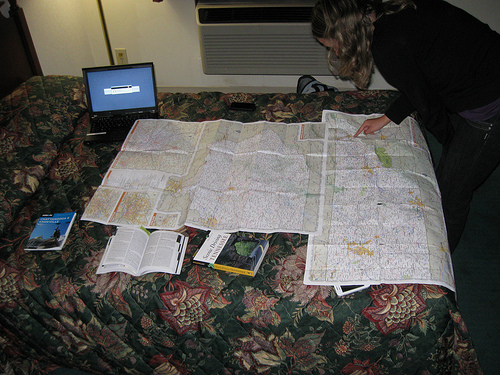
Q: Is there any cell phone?
A: Yes, there is a cell phone.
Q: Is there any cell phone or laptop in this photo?
A: Yes, there is a cell phone.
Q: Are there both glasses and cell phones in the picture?
A: No, there is a cell phone but no glasses.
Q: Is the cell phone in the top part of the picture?
A: Yes, the cell phone is in the top of the image.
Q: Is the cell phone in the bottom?
A: No, the cell phone is in the top of the image.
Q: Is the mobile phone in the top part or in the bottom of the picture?
A: The mobile phone is in the top of the image.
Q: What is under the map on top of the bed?
A: The cell phone is under the map.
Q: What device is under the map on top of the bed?
A: The device is a cell phone.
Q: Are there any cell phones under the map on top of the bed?
A: Yes, there is a cell phone under the map.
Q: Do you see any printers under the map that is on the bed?
A: No, there is a cell phone under the map.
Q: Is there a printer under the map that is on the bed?
A: No, there is a cell phone under the map.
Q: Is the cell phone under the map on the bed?
A: Yes, the cell phone is under the map.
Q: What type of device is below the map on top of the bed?
A: The device is a cell phone.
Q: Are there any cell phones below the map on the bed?
A: Yes, there is a cell phone below the map.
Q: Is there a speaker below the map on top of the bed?
A: No, there is a cell phone below the map.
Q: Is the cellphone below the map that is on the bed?
A: Yes, the cellphone is below the map.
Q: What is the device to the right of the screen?
A: The device is a cell phone.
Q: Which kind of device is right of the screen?
A: The device is a cell phone.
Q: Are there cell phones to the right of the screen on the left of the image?
A: Yes, there is a cell phone to the right of the screen.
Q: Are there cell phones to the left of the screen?
A: No, the cell phone is to the right of the screen.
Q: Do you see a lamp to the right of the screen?
A: No, there is a cell phone to the right of the screen.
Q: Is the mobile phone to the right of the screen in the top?
A: Yes, the mobile phone is to the right of the screen.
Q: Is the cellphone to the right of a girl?
A: No, the cellphone is to the right of the screen.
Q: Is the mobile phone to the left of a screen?
A: No, the mobile phone is to the right of a screen.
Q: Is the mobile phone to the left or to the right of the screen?
A: The mobile phone is to the right of the screen.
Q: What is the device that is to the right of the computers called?
A: The device is a cell phone.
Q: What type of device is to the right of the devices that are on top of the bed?
A: The device is a cell phone.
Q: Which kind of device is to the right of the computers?
A: The device is a cell phone.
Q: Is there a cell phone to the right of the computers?
A: Yes, there is a cell phone to the right of the computers.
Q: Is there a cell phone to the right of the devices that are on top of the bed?
A: Yes, there is a cell phone to the right of the computers.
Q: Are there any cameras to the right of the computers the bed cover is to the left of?
A: No, there is a cell phone to the right of the computers.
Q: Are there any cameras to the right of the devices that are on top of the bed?
A: No, there is a cell phone to the right of the computers.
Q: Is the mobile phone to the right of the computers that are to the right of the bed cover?
A: Yes, the mobile phone is to the right of the computers.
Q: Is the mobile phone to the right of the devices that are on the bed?
A: Yes, the mobile phone is to the right of the computers.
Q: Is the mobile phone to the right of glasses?
A: No, the mobile phone is to the right of the computers.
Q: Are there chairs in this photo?
A: No, there are no chairs.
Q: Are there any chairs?
A: No, there are no chairs.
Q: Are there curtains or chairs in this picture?
A: No, there are no chairs or curtains.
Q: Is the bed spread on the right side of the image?
A: No, the bed spread is on the left of the image.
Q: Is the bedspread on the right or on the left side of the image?
A: The bedspread is on the left of the image.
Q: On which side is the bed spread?
A: The bed spread is on the left of the image.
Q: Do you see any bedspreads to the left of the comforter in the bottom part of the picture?
A: Yes, there is a bedspread to the left of the bed cover.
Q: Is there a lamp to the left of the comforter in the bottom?
A: No, there is a bedspread to the left of the comforter.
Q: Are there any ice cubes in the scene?
A: No, there are no ice cubes.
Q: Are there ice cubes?
A: No, there are no ice cubes.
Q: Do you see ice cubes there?
A: No, there are no ice cubes.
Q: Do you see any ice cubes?
A: No, there are no ice cubes.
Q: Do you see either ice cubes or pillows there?
A: No, there are no ice cubes or pillows.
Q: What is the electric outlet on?
A: The electric outlet is on the wall.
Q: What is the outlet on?
A: The electric outlet is on the wall.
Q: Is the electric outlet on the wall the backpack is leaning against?
A: Yes, the electric outlet is on the wall.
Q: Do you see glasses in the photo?
A: No, there are no glasses.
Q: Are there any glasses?
A: No, there are no glasses.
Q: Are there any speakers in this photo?
A: No, there are no speakers.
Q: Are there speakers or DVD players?
A: No, there are no speakers or DVD players.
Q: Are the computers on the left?
A: Yes, the computers are on the left of the image.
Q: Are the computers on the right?
A: No, the computers are on the left of the image.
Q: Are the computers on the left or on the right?
A: The computers are on the left of the image.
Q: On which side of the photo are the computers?
A: The computers are on the left of the image.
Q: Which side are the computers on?
A: The computers are on the left of the image.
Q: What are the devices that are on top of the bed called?
A: The devices are computers.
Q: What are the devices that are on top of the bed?
A: The devices are computers.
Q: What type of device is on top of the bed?
A: The devices are computers.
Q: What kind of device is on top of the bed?
A: The devices are computers.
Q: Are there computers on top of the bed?
A: Yes, there are computers on top of the bed.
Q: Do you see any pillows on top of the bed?
A: No, there are computers on top of the bed.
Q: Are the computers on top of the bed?
A: Yes, the computers are on top of the bed.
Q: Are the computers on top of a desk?
A: No, the computers are on top of the bed.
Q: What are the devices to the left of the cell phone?
A: The devices are computers.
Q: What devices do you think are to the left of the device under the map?
A: The devices are computers.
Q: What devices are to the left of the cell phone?
A: The devices are computers.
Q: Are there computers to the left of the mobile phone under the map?
A: Yes, there are computers to the left of the mobile phone.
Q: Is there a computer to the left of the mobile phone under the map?
A: Yes, there are computers to the left of the mobile phone.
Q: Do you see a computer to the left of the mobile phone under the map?
A: Yes, there are computers to the left of the mobile phone.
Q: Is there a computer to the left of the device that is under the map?
A: Yes, there are computers to the left of the mobile phone.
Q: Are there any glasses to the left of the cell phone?
A: No, there are computers to the left of the cell phone.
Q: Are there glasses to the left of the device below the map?
A: No, there are computers to the left of the cell phone.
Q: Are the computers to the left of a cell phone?
A: Yes, the computers are to the left of a cell phone.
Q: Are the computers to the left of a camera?
A: No, the computers are to the left of a cell phone.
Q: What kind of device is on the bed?
A: The devices are computers.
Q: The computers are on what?
A: The computers are on the bed.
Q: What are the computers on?
A: The computers are on the bed.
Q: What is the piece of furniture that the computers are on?
A: The piece of furniture is a bed.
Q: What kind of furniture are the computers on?
A: The computers are on the bed.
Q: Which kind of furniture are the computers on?
A: The computers are on the bed.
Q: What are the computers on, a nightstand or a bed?
A: The computers are on a bed.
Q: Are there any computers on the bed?
A: Yes, there are computers on the bed.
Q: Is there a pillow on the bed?
A: No, there are computers on the bed.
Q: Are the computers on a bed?
A: Yes, the computers are on a bed.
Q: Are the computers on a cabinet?
A: No, the computers are on a bed.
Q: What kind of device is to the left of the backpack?
A: The devices are computers.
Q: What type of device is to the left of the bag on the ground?
A: The devices are computers.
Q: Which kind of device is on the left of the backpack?
A: The devices are computers.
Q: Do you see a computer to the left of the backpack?
A: Yes, there are computers to the left of the backpack.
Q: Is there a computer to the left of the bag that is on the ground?
A: Yes, there are computers to the left of the backpack.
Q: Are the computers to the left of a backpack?
A: Yes, the computers are to the left of a backpack.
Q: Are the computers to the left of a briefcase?
A: No, the computers are to the left of a backpack.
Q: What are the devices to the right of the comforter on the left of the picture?
A: The devices are computers.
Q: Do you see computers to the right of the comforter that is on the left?
A: Yes, there are computers to the right of the comforter.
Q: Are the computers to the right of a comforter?
A: Yes, the computers are to the right of a comforter.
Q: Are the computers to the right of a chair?
A: No, the computers are to the right of a comforter.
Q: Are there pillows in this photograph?
A: No, there are no pillows.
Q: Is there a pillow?
A: No, there are no pillows.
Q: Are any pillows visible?
A: No, there are no pillows.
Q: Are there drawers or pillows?
A: No, there are no pillows or drawers.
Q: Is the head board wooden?
A: Yes, the head board is wooden.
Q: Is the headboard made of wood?
A: Yes, the headboard is made of wood.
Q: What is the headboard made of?
A: The headboard is made of wood.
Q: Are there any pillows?
A: No, there are no pillows.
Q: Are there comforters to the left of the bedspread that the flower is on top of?
A: Yes, there is a comforter to the left of the bedspread.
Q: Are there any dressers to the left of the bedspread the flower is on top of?
A: No, there is a comforter to the left of the bedspread.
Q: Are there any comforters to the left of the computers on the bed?
A: Yes, there is a comforter to the left of the computers.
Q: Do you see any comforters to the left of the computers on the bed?
A: Yes, there is a comforter to the left of the computers.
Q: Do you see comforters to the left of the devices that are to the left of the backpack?
A: Yes, there is a comforter to the left of the computers.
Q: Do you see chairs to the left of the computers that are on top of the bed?
A: No, there is a comforter to the left of the computers.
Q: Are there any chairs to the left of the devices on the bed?
A: No, there is a comforter to the left of the computers.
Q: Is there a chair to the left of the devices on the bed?
A: No, there is a comforter to the left of the computers.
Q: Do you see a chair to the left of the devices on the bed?
A: No, there is a comforter to the left of the computers.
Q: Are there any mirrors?
A: No, there are no mirrors.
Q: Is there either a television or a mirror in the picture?
A: No, there are no mirrors or televisions.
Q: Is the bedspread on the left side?
A: Yes, the bedspread is on the left of the image.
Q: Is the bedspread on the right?
A: No, the bedspread is on the left of the image.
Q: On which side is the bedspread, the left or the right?
A: The bedspread is on the left of the image.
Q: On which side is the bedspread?
A: The bedspread is on the left of the image.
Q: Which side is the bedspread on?
A: The bedspread is on the left of the image.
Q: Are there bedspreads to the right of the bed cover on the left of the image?
A: Yes, there is a bedspread to the right of the bed cover.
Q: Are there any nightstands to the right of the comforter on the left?
A: No, there is a bedspread to the right of the quilt.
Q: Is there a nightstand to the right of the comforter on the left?
A: No, there is a bedspread to the right of the quilt.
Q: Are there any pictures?
A: No, there are no pictures.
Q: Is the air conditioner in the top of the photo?
A: Yes, the air conditioner is in the top of the image.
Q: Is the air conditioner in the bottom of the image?
A: No, the air conditioner is in the top of the image.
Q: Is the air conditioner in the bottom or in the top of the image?
A: The air conditioner is in the top of the image.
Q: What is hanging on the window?
A: The air conditioner is hanging on the window.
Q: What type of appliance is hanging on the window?
A: The appliance is an air conditioner.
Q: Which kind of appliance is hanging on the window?
A: The appliance is an air conditioner.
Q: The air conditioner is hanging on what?
A: The air conditioner is hanging on the window.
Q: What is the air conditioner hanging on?
A: The air conditioner is hanging on the window.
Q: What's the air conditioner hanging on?
A: The air conditioner is hanging on the window.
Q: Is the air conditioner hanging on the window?
A: Yes, the air conditioner is hanging on the window.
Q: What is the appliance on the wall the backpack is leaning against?
A: The appliance is an air conditioner.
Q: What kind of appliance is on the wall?
A: The appliance is an air conditioner.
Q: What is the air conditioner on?
A: The air conditioner is on the wall.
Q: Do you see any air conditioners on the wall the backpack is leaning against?
A: Yes, there is an air conditioner on the wall.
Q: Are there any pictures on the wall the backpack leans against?
A: No, there is an air conditioner on the wall.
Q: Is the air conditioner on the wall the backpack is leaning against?
A: Yes, the air conditioner is on the wall.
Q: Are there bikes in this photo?
A: No, there are no bikes.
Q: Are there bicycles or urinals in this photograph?
A: No, there are no bicycles or urinals.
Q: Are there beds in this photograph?
A: Yes, there is a bed.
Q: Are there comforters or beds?
A: Yes, there is a bed.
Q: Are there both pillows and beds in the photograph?
A: No, there is a bed but no pillows.